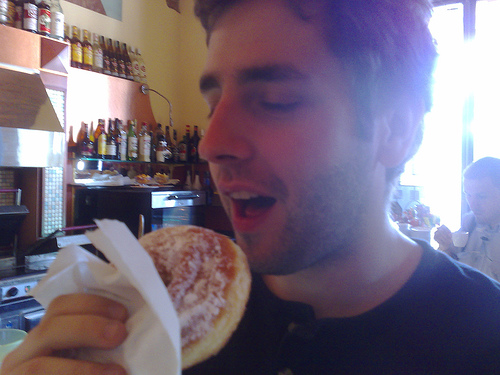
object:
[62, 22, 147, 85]
bottles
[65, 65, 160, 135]
shelf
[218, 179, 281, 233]
mouth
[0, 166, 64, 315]
oven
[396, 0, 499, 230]
sunlight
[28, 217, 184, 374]
napkin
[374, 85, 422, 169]
ear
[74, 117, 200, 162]
syrups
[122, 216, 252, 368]
doughnut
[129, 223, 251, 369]
donut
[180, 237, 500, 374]
black shirt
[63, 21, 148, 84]
coffee syrups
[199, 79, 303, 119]
eyes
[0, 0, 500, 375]
man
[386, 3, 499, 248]
windows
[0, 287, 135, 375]
hand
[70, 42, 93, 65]
labels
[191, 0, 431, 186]
hair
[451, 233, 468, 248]
cup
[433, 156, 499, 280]
patron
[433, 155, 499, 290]
man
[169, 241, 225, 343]
sugar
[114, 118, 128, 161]
bottle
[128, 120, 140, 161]
bottle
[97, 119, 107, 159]
bottle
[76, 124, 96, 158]
bottle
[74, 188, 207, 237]
oven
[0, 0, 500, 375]
restaurant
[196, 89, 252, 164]
nose